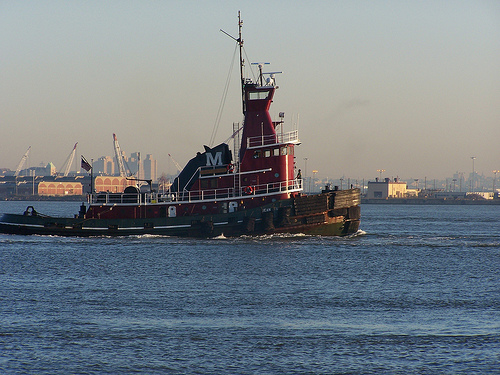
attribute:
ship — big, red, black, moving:
[3, 9, 369, 225]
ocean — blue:
[1, 196, 495, 374]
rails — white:
[90, 173, 304, 204]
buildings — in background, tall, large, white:
[82, 136, 165, 183]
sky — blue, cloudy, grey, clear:
[8, 1, 492, 164]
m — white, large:
[206, 152, 225, 166]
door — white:
[168, 207, 176, 217]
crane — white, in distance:
[111, 132, 128, 180]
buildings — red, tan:
[21, 176, 128, 195]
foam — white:
[131, 233, 228, 241]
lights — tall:
[309, 170, 498, 177]